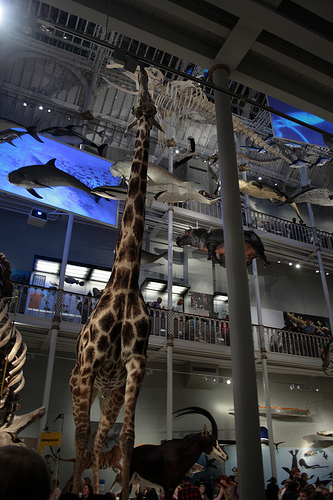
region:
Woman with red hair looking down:
[219, 475, 231, 488]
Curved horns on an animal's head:
[172, 403, 222, 441]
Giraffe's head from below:
[129, 69, 158, 123]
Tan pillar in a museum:
[223, 265, 271, 498]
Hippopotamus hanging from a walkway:
[170, 226, 267, 273]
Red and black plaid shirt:
[177, 486, 201, 499]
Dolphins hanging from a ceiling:
[3, 124, 154, 211]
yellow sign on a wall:
[38, 428, 62, 449]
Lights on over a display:
[33, 257, 191, 298]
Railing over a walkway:
[168, 307, 234, 344]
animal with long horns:
[127, 399, 228, 492]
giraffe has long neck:
[98, 54, 160, 304]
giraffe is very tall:
[57, 65, 170, 496]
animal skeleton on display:
[0, 244, 48, 444]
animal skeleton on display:
[114, 54, 296, 169]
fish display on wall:
[241, 401, 313, 418]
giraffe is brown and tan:
[67, 59, 167, 495]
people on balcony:
[3, 271, 331, 355]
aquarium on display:
[2, 119, 125, 224]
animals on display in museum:
[21, 36, 332, 497]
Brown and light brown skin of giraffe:
[102, 303, 129, 333]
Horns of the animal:
[181, 406, 218, 430]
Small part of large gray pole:
[230, 359, 257, 423]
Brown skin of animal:
[155, 453, 172, 470]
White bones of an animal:
[154, 78, 201, 118]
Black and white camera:
[28, 207, 46, 227]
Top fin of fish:
[45, 156, 57, 165]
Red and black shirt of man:
[181, 486, 197, 497]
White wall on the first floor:
[209, 389, 221, 404]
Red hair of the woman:
[221, 475, 227, 481]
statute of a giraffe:
[64, 54, 159, 498]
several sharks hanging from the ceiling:
[1, 103, 323, 220]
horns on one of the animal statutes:
[166, 400, 225, 435]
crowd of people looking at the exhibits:
[52, 459, 329, 499]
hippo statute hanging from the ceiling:
[172, 220, 274, 273]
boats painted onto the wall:
[226, 391, 332, 449]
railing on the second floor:
[9, 279, 332, 348]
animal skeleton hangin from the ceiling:
[101, 53, 311, 171]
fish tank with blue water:
[1, 120, 122, 225]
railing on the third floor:
[129, 169, 332, 252]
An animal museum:
[8, 19, 317, 496]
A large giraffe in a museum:
[67, 55, 183, 497]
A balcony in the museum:
[27, 260, 318, 357]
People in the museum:
[44, 455, 331, 499]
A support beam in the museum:
[197, 56, 277, 497]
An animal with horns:
[130, 393, 238, 486]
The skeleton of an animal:
[109, 42, 304, 175]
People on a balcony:
[142, 280, 194, 337]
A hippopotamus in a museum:
[173, 214, 277, 274]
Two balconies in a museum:
[142, 177, 320, 380]